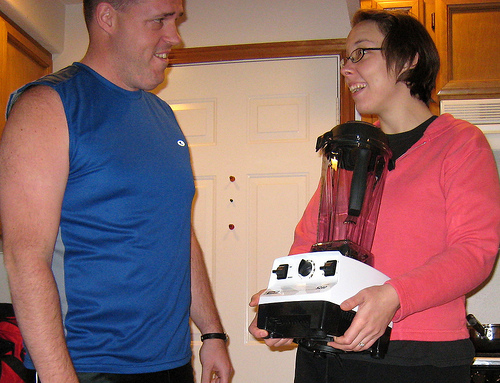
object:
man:
[2, 2, 240, 382]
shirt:
[2, 63, 196, 376]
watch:
[197, 330, 230, 343]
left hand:
[195, 330, 236, 382]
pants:
[21, 358, 205, 383]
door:
[152, 53, 342, 383]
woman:
[246, 5, 497, 383]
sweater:
[287, 115, 498, 344]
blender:
[254, 119, 396, 359]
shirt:
[378, 110, 435, 167]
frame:
[187, 41, 346, 62]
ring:
[356, 341, 369, 349]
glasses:
[335, 47, 382, 66]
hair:
[351, 10, 441, 105]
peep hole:
[226, 196, 239, 205]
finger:
[357, 333, 375, 356]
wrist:
[197, 331, 228, 340]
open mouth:
[346, 83, 370, 98]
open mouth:
[149, 49, 172, 63]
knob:
[298, 258, 313, 274]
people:
[0, 0, 237, 383]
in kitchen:
[0, 0, 499, 383]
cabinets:
[360, 0, 498, 134]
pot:
[466, 310, 499, 352]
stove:
[471, 343, 500, 376]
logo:
[173, 137, 189, 149]